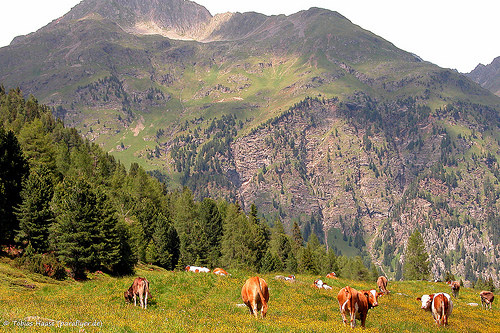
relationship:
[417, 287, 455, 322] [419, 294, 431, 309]
brown cow with white face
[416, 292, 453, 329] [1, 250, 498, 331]
brown cow on grass field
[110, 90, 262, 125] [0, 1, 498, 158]
grass on mountains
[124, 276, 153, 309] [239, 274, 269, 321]
cow eating cow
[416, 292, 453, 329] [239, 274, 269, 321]
brown cow eating cow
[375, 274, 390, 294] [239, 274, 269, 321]
cow eating cow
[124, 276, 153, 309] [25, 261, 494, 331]
cow is eating grass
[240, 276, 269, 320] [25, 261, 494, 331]
cow is eating grass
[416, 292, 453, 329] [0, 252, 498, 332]
brown cow in field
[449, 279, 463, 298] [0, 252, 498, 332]
cows in field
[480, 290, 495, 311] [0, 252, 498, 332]
cows in field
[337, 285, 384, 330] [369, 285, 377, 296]
cow has spot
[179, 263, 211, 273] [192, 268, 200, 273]
cow with spots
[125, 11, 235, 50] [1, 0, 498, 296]
sunshine on mountain side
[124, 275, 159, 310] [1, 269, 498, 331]
cow eat grass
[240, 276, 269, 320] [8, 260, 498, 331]
cow on field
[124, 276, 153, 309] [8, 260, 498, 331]
cow on field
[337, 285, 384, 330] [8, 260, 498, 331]
cow on field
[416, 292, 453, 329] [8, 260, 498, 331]
brown cow on field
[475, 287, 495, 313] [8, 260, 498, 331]
cows on field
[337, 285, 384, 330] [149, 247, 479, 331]
cow grazing in field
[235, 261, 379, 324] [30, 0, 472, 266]
cow grazing on green grass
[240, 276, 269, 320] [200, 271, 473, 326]
cow laying down grass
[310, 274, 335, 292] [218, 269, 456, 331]
cow laying in grass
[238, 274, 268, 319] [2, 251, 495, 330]
cow in grass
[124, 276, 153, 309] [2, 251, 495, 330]
cow in grass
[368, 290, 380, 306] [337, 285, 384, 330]
face of a cow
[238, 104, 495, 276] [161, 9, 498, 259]
cliff on side of mountain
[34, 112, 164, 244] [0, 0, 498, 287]
tree in mountain